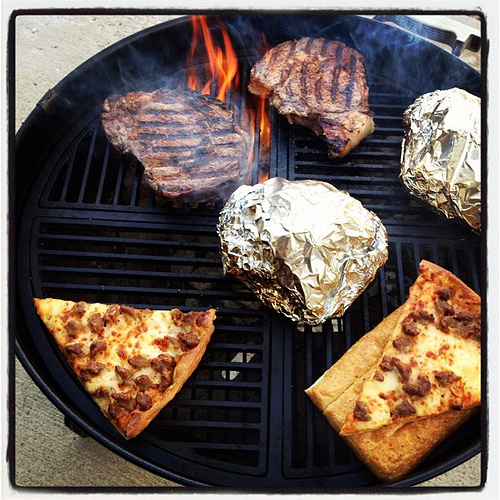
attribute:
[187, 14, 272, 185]
flames — red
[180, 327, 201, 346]
sausage — brown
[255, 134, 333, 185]
metal grill — black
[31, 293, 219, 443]
pizza — peice, grilled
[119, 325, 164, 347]
cheese — white, melted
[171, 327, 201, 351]
sausage — brown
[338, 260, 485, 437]
pizza — sliced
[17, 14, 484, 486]
barbeque — black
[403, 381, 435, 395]
sausage — brown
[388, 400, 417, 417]
sausage — brown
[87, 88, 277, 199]
meat — peice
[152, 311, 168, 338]
cheese — white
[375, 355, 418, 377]
sausage — brown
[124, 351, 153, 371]
sausage — brown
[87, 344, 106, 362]
sausage — brown